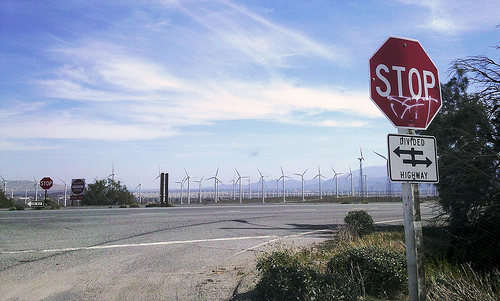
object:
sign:
[388, 134, 439, 183]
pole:
[397, 127, 420, 301]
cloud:
[0, 101, 218, 141]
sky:
[0, 0, 500, 190]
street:
[0, 202, 440, 301]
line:
[0, 234, 277, 254]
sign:
[368, 35, 443, 130]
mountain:
[0, 180, 72, 193]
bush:
[77, 177, 142, 205]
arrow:
[401, 157, 433, 169]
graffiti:
[387, 94, 439, 127]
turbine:
[312, 164, 328, 200]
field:
[147, 196, 439, 202]